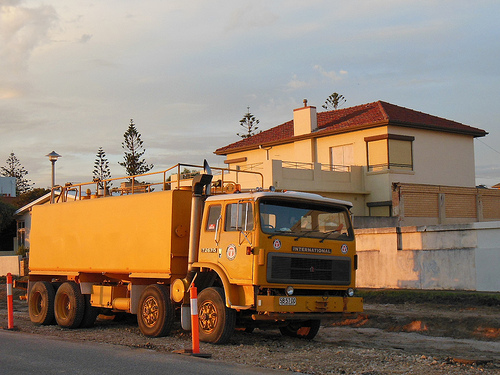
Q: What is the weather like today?
A: It is cloudy.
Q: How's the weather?
A: It is cloudy.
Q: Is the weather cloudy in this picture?
A: Yes, it is cloudy.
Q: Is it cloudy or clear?
A: It is cloudy.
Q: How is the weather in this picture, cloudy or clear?
A: It is cloudy.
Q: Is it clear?
A: No, it is cloudy.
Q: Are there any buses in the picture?
A: No, there are no buses.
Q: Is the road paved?
A: Yes, the road is paved.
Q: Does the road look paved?
A: Yes, the road is paved.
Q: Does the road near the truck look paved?
A: Yes, the road is paved.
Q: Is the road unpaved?
A: No, the road is paved.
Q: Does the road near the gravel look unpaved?
A: No, the road is paved.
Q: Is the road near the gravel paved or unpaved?
A: The road is paved.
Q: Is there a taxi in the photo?
A: Yes, there is a taxi.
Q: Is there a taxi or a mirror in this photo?
A: Yes, there is a taxi.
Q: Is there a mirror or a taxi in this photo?
A: Yes, there is a taxi.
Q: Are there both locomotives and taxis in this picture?
A: No, there is a taxi but no locomotives.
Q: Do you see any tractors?
A: No, there are no tractors.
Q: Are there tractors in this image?
A: No, there are no tractors.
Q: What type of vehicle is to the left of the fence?
A: The vehicle is a taxi.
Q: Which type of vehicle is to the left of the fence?
A: The vehicle is a taxi.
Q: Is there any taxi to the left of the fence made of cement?
A: Yes, there is a taxi to the left of the fence.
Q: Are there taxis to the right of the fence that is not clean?
A: No, the taxi is to the left of the fence.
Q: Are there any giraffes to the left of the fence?
A: No, there is a taxi to the left of the fence.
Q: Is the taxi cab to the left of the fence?
A: Yes, the taxi cab is to the left of the fence.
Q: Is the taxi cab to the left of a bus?
A: No, the taxi cab is to the left of the fence.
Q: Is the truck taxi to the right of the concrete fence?
A: No, the taxi is to the left of the fence.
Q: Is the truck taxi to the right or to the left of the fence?
A: The taxi is to the left of the fence.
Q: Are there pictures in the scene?
A: No, there are no pictures.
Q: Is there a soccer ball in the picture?
A: No, there are no soccer balls.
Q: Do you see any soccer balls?
A: No, there are no soccer balls.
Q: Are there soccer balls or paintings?
A: No, there are no soccer balls or paintings.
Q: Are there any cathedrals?
A: No, there are no cathedrals.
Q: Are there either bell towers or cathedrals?
A: No, there are no cathedrals or bell towers.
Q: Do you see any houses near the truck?
A: Yes, there is a house near the truck.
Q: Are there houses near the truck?
A: Yes, there is a house near the truck.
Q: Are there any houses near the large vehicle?
A: Yes, there is a house near the truck.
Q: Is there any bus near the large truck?
A: No, there is a house near the truck.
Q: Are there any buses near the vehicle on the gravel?
A: No, there is a house near the truck.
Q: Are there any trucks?
A: Yes, there is a truck.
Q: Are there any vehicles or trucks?
A: Yes, there is a truck.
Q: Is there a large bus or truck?
A: Yes, there is a large truck.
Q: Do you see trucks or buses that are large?
A: Yes, the truck is large.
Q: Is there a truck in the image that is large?
A: Yes, there is a large truck.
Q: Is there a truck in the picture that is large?
A: Yes, there is a truck that is large.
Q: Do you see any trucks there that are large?
A: Yes, there is a truck that is large.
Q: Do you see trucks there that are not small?
A: Yes, there is a large truck.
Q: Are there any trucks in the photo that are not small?
A: Yes, there is a large truck.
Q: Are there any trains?
A: No, there are no trains.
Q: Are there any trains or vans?
A: No, there are no trains or vans.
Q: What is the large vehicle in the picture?
A: The vehicle is a truck.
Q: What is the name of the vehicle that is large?
A: The vehicle is a truck.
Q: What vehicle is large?
A: The vehicle is a truck.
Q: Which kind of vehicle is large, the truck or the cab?
A: The truck is large.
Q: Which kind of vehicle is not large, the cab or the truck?
A: The cab is not large.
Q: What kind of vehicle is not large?
A: The vehicle is a taxi.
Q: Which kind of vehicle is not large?
A: The vehicle is a taxi.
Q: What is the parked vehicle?
A: The vehicle is a truck.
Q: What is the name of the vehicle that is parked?
A: The vehicle is a truck.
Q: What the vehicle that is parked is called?
A: The vehicle is a truck.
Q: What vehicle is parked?
A: The vehicle is a truck.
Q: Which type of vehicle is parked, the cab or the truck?
A: The truck is parked.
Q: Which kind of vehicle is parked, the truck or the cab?
A: The truck is parked.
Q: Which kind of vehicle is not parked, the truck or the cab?
A: The cab is not parked.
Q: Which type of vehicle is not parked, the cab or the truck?
A: The cab is not parked.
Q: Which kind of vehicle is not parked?
A: The vehicle is a taxi.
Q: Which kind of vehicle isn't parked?
A: The vehicle is a taxi.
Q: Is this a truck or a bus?
A: This is a truck.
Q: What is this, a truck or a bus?
A: This is a truck.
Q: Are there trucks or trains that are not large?
A: No, there is a truck but it is large.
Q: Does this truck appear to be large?
A: Yes, the truck is large.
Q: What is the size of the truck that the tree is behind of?
A: The truck is large.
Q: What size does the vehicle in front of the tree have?
A: The truck has large size.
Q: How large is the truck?
A: The truck is large.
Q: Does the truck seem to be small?
A: No, the truck is large.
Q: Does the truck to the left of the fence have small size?
A: No, the truck is large.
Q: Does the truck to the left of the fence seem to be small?
A: No, the truck is large.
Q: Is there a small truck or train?
A: No, there is a truck but it is large.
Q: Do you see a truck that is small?
A: No, there is a truck but it is large.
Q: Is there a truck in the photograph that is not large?
A: No, there is a truck but it is large.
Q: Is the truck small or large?
A: The truck is large.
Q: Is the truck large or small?
A: The truck is large.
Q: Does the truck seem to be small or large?
A: The truck is large.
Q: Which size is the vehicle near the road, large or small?
A: The truck is large.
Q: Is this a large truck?
A: Yes, this is a large truck.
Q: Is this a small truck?
A: No, this is a large truck.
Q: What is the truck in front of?
A: The truck is in front of the tree.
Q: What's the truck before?
A: The truck is in front of the tree.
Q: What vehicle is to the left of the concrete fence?
A: The vehicle is a truck.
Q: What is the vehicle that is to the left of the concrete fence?
A: The vehicle is a truck.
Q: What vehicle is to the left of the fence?
A: The vehicle is a truck.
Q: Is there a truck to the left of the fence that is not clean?
A: Yes, there is a truck to the left of the fence.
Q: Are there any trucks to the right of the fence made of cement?
A: No, the truck is to the left of the fence.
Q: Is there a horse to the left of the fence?
A: No, there is a truck to the left of the fence.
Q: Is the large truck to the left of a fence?
A: Yes, the truck is to the left of a fence.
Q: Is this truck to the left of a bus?
A: No, the truck is to the left of a fence.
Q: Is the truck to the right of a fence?
A: No, the truck is to the left of a fence.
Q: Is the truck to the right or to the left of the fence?
A: The truck is to the left of the fence.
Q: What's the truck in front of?
A: The truck is in front of the tree.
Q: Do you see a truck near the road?
A: Yes, there is a truck near the road.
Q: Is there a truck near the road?
A: Yes, there is a truck near the road.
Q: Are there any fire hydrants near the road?
A: No, there is a truck near the road.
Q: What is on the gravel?
A: The truck is on the gravel.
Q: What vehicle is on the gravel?
A: The vehicle is a truck.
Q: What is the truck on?
A: The truck is on the gravel.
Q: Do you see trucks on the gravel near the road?
A: Yes, there is a truck on the gravel.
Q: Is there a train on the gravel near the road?
A: No, there is a truck on the gravel.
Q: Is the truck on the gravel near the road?
A: Yes, the truck is on the gravel.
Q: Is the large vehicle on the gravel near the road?
A: Yes, the truck is on the gravel.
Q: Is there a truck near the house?
A: Yes, there is a truck near the house.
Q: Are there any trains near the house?
A: No, there is a truck near the house.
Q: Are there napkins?
A: No, there are no napkins.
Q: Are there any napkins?
A: No, there are no napkins.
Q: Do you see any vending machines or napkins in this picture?
A: No, there are no napkins or vending machines.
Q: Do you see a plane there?
A: No, there are no airplanes.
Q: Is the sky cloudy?
A: Yes, the sky is cloudy.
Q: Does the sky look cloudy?
A: Yes, the sky is cloudy.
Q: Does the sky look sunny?
A: No, the sky is cloudy.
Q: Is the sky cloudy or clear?
A: The sky is cloudy.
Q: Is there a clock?
A: No, there are no clocks.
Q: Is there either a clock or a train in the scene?
A: No, there are no clocks or trains.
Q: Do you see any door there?
A: Yes, there is a door.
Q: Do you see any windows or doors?
A: Yes, there is a door.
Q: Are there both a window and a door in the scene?
A: Yes, there are both a door and a window.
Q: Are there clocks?
A: No, there are no clocks.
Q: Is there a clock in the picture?
A: No, there are no clocks.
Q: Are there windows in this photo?
A: Yes, there is a window.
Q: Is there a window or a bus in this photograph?
A: Yes, there is a window.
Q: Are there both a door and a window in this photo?
A: Yes, there are both a window and a door.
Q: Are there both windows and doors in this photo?
A: Yes, there are both a window and a door.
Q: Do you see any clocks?
A: No, there are no clocks.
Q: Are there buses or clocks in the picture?
A: No, there are no clocks or buses.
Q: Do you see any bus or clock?
A: No, there are no clocks or buses.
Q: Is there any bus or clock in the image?
A: No, there are no clocks or buses.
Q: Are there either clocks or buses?
A: No, there are no clocks or buses.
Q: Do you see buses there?
A: No, there are no buses.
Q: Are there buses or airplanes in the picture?
A: No, there are no buses or airplanes.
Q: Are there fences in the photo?
A: Yes, there is a fence.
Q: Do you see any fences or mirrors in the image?
A: Yes, there is a fence.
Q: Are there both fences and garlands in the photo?
A: No, there is a fence but no garlands.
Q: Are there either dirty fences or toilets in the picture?
A: Yes, there is a dirty fence.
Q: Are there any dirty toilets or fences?
A: Yes, there is a dirty fence.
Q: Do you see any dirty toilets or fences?
A: Yes, there is a dirty fence.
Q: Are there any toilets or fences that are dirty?
A: Yes, the fence is dirty.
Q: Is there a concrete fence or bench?
A: Yes, there is a concrete fence.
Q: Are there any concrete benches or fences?
A: Yes, there is a concrete fence.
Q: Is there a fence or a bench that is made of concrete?
A: Yes, the fence is made of concrete.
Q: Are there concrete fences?
A: Yes, there is a fence that is made of concrete.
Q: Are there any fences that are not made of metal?
A: Yes, there is a fence that is made of concrete.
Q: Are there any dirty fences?
A: Yes, there is a dirty fence.